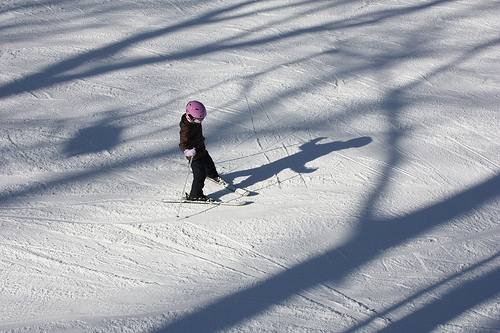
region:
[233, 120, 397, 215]
skier's shadow on the snow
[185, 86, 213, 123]
purple ski helmet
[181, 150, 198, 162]
lavender ski glove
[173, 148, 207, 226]
holding on to ski pole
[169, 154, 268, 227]
skis turned towards each other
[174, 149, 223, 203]
ski pants are black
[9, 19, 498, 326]
tree shadows on the snow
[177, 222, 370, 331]
ski marks in the snow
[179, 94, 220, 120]
skier looking at skis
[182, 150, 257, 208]
ski pants are black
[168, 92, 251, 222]
kid skiing in the snow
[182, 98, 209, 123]
pink helmet on the girl's head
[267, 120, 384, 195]
shadow of the kid on the snow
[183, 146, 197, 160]
mittens on the hand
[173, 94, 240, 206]
kid wearing a brown jacket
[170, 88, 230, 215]
kid wearing black skiipants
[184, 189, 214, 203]
ski boots on the girl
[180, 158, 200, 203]
ski poles in the hand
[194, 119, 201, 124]
goggles on the girl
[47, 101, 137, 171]
shadows on the snow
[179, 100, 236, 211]
a skier skiing in the snow.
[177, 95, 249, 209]
a skier skiing in the snow.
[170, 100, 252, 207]
a skier skiing in the snow.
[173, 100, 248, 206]
a skier skiing in the snow.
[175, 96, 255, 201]
a skier skiing in the snow.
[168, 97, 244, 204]
a skier skiing in the snow.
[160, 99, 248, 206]
a skier skiing in the snow.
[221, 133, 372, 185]
the shadow of the person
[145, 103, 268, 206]
a person skiing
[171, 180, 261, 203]
the skis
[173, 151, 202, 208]
the ski pole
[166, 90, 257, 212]
a person skiing down a hill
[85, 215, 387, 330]
tracks in the snow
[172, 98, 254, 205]
a person wearing a pink helmet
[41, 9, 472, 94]
shadows on the snow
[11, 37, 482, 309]
A person is up in the mountains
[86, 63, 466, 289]
A person is out in the snow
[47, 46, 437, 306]
A person is doing some skiing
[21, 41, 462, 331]
A person is having a good time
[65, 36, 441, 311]
A person is casting a shadow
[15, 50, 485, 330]
A person is using snow skis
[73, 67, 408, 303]
A person is wearing warm clothing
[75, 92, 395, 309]
A person is wearing a helmet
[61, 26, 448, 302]
A person is out in the daytime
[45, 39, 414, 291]
A person is enjoying their day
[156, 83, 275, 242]
young boy skiing down a gentle slope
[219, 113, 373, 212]
shadow of the young skier on the ground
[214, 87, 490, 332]
shadow of the trees on the snow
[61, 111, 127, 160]
dark shadow on the snowy slope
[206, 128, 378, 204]
dark shadow on the snowy slope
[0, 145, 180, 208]
dark shadow on the snowy slope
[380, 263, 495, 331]
dark shadow on the snowy slope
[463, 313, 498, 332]
dark shadow on the snowy slope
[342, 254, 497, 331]
dark shadow on the snowy slope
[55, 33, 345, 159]
dark shadow on the snowy slope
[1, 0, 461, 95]
dark shadow on the snowy slope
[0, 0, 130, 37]
dark shadow on the snowy slope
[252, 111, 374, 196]
a shadow on the snow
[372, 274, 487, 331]
a shadow on the snow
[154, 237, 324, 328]
a shadow on the snow